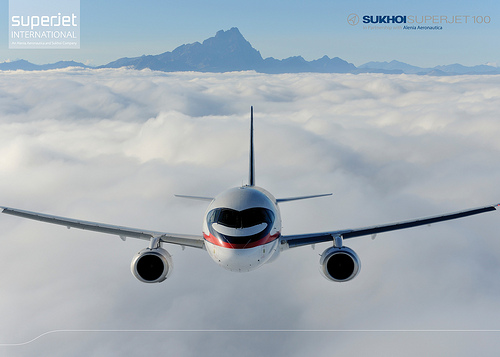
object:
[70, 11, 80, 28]
letter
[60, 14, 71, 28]
letter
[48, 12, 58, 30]
letter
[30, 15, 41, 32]
letter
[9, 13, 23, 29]
letter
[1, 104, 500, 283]
plane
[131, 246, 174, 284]
jet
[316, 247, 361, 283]
jet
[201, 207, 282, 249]
front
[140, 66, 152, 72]
clouds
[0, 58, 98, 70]
mountain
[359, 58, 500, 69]
mountain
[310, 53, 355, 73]
mountain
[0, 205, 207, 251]
wing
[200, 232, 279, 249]
line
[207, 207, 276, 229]
windshield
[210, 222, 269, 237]
line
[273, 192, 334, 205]
tail wing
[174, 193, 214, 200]
tail wing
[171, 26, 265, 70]
tall mountain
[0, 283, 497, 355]
several clouds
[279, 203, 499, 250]
long wing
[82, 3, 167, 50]
sky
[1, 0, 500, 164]
sky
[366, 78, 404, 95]
clouds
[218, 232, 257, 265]
nose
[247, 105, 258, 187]
tail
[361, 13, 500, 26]
name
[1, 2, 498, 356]
photo